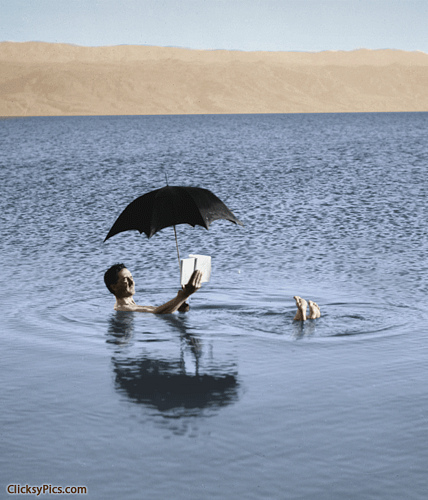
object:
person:
[104, 260, 320, 326]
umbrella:
[103, 171, 240, 305]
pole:
[172, 228, 180, 267]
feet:
[293, 295, 309, 321]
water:
[0, 113, 427, 499]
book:
[180, 252, 210, 289]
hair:
[105, 261, 129, 296]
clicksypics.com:
[4, 480, 91, 498]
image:
[0, 0, 427, 500]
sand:
[0, 37, 427, 115]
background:
[0, 0, 427, 499]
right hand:
[179, 268, 201, 297]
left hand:
[174, 302, 191, 315]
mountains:
[0, 40, 427, 116]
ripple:
[0, 111, 427, 315]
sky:
[0, 0, 427, 54]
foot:
[307, 299, 321, 318]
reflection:
[110, 336, 240, 424]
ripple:
[36, 282, 427, 351]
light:
[0, 284, 427, 500]